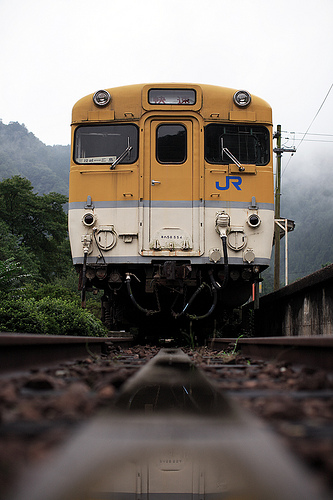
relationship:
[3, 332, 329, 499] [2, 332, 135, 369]
tracks made of iron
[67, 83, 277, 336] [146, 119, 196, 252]
bus has a door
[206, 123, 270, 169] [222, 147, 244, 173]
window has a wiper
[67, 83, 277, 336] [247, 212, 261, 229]
bus has a headlight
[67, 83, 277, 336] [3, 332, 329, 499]
bus on tracks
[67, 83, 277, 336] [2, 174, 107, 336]
bus in front of trees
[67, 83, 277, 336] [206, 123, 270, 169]
bus has a window